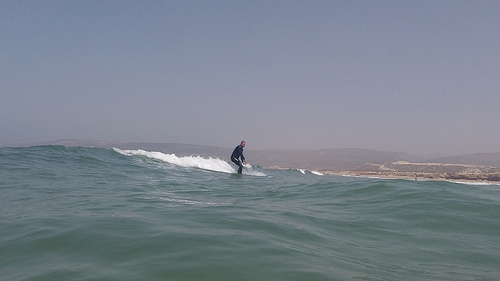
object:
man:
[229, 140, 247, 175]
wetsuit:
[230, 146, 246, 173]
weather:
[3, 10, 491, 270]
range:
[130, 135, 496, 170]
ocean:
[0, 146, 500, 277]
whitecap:
[112, 147, 234, 173]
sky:
[0, 4, 500, 139]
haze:
[5, 85, 497, 133]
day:
[2, 5, 496, 275]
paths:
[361, 163, 397, 172]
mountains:
[414, 151, 499, 167]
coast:
[258, 163, 500, 188]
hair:
[240, 140, 246, 144]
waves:
[110, 136, 232, 178]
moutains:
[314, 143, 380, 171]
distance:
[11, 4, 499, 182]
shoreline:
[0, 143, 500, 192]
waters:
[0, 147, 499, 276]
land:
[108, 137, 498, 175]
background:
[3, 4, 499, 177]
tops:
[108, 133, 500, 164]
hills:
[36, 135, 114, 147]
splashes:
[308, 169, 324, 176]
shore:
[332, 175, 500, 187]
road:
[391, 160, 472, 168]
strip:
[278, 178, 362, 188]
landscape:
[0, 130, 498, 181]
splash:
[296, 169, 306, 175]